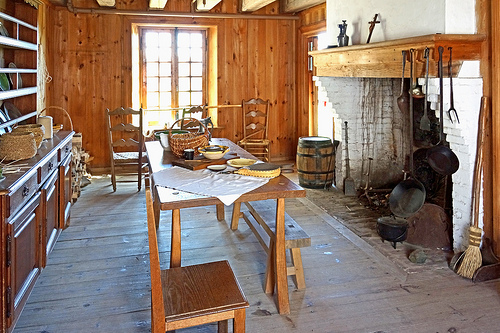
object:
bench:
[229, 199, 311, 293]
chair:
[105, 106, 151, 192]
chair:
[145, 187, 249, 333]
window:
[137, 27, 208, 128]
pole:
[293, 20, 296, 158]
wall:
[53, 5, 305, 173]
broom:
[451, 96, 489, 279]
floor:
[11, 169, 499, 333]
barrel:
[296, 136, 335, 189]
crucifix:
[367, 14, 381, 44]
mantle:
[307, 33, 484, 79]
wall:
[314, 0, 499, 258]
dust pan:
[449, 237, 500, 284]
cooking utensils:
[389, 46, 459, 218]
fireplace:
[307, 36, 500, 257]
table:
[144, 137, 312, 315]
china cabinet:
[0, 0, 76, 333]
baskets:
[0, 124, 46, 162]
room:
[1, 0, 500, 333]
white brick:
[310, 75, 396, 190]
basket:
[168, 117, 210, 159]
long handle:
[409, 48, 414, 178]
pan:
[388, 48, 425, 218]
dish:
[227, 158, 258, 167]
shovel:
[345, 121, 359, 197]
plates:
[0, 62, 23, 91]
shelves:
[0, 0, 44, 159]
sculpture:
[337, 20, 349, 48]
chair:
[236, 97, 271, 163]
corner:
[447, 0, 500, 284]